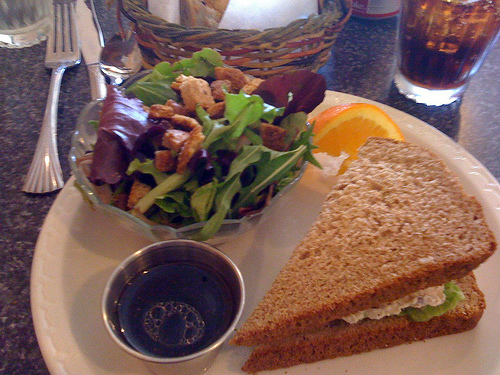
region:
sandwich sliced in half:
[268, 209, 432, 339]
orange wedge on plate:
[315, 92, 400, 182]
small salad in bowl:
[126, 72, 281, 236]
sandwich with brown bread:
[312, 186, 468, 359]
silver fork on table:
[27, 17, 68, 197]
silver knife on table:
[77, 16, 128, 116]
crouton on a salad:
[173, 126, 200, 172]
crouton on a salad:
[153, 151, 178, 176]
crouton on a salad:
[161, 129, 189, 147]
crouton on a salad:
[148, 103, 176, 118]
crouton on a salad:
[176, 75, 213, 109]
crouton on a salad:
[209, 77, 227, 95]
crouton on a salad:
[215, 65, 242, 86]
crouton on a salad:
[258, 121, 283, 145]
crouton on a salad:
[123, 179, 152, 215]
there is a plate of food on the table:
[14, 77, 497, 372]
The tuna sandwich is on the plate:
[234, 135, 497, 343]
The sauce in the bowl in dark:
[93, 233, 253, 361]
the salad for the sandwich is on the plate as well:
[68, 80, 322, 238]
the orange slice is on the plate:
[311, 94, 418, 179]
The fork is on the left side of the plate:
[25, 4, 76, 196]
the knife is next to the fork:
[77, 8, 119, 136]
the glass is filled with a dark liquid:
[384, 3, 498, 117]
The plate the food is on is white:
[22, 56, 497, 373]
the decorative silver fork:
[22, 1, 78, 191]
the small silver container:
[101, 239, 246, 373]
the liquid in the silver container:
[102, 237, 244, 372]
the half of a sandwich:
[230, 135, 495, 372]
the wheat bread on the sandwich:
[225, 137, 497, 373]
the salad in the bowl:
[68, 47, 326, 243]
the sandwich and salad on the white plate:
[30, 47, 497, 372]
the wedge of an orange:
[305, 100, 405, 167]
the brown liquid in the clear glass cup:
[392, 0, 497, 106]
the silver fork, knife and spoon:
[20, 1, 144, 192]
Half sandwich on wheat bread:
[241, 132, 490, 368]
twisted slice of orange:
[314, 98, 397, 160]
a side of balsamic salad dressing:
[115, 258, 234, 355]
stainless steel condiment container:
[105, 235, 241, 355]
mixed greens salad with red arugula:
[88, 43, 333, 219]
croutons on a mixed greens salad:
[116, 58, 258, 213]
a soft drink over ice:
[391, 0, 498, 120]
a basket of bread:
[116, 0, 350, 70]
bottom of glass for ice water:
[1, 0, 51, 46]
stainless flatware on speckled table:
[22, 1, 144, 194]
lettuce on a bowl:
[220, 85, 266, 138]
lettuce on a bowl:
[195, 103, 229, 148]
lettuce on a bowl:
[216, 140, 263, 186]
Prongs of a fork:
[37, 0, 83, 72]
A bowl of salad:
[57, 45, 337, 255]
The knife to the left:
[24, 13, 71, 191]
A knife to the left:
[60, 12, 138, 115]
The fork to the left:
[25, 16, 86, 196]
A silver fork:
[27, 15, 74, 203]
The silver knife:
[66, 12, 126, 114]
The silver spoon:
[96, 32, 152, 101]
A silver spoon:
[95, 29, 144, 104]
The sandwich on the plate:
[267, 133, 498, 355]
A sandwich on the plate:
[248, 141, 486, 368]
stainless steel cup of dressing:
[101, 236, 243, 370]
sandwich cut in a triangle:
[239, 135, 493, 373]